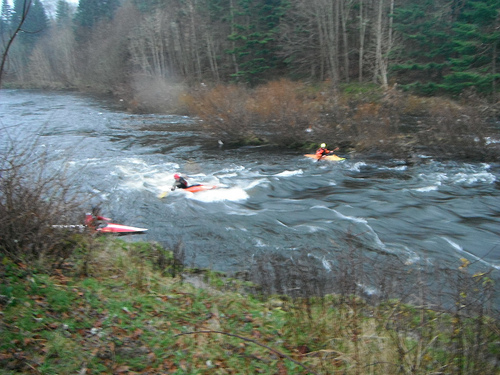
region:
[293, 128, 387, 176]
person kayaking in a river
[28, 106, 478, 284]
people in kayaks on a river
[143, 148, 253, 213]
kayak stuck in some rapids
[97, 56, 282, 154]
dead or dry vegetation along a river's edge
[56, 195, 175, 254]
person in a red and white kayak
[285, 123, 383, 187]
person paddling in a kayak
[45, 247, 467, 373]
grass and weeds by the river bank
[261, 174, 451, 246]
waves and rapids in the river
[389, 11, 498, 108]
evergreen trees in the woods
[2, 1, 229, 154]
river running through a wooded area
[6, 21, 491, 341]
rapid flowing stream in nature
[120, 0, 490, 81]
bare trees, evergreens and shrubs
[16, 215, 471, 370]
bare shrubs, weeds and reeds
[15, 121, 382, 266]
three people in kayaks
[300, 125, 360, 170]
person in white helmet near the edge of stream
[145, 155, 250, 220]
person in orange helmet in middle of stream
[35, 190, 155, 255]
person on side of stream near land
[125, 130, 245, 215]
white water surrounding kayak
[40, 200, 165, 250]
orange and white kayak pointing toward water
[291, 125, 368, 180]
person sitting upright in calm water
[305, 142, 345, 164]
person in a kayak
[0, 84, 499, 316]
kayak in a river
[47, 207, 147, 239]
kayak near the river bank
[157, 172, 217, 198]
person in kayak going over rapids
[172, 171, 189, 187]
person wearing a dark jacket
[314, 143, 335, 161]
person wearing an orange jacket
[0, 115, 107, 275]
bare bush next to river bank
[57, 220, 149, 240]
kayak is white and red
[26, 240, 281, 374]
grass next to river bank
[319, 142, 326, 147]
person wearing white helmet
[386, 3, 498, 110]
a tall evergreen tree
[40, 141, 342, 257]
a trio of solo kayaking people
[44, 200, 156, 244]
a kayaker close to shore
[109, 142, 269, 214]
a kayaker in choppy water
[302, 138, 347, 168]
a kayaker with a yellow helmet and orange jacket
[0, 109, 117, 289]
a bush without any leaves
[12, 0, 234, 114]
a row of trees without leaves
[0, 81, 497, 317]
a rapidly flowing river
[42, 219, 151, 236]
an orange kayak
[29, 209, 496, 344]
the shore of a river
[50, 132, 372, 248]
Three kayaks in the water.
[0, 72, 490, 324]
River flowing down stream.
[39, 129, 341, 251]
Three people in the river.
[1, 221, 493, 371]
River bank close to the water.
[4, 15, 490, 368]
Photo taken during the day.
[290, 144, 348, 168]
One yellow kayak.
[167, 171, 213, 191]
Kayaker wearing a helmet.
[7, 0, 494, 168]
Photo taken in the fall.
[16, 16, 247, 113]
Trees without leaves.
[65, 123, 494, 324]
Waves in the river.